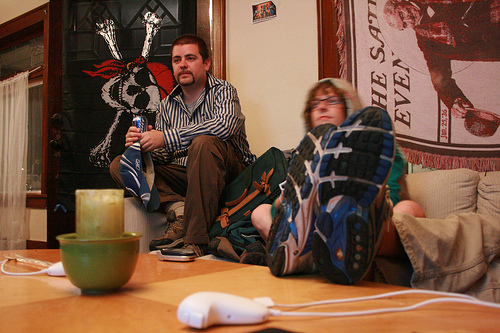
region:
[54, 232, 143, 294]
green bowl on coffee table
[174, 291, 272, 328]
white Wii nunchuck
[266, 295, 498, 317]
white wire attached to Wii nunchuck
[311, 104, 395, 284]
sole of shoe is black and blue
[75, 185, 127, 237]
green candle in green bowl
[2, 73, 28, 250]
sheer white curtain is hanging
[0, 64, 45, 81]
curtain on curtain rod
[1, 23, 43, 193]
curtain on window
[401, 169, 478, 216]
tan sofa cushion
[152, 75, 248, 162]
striped long sleeve shirt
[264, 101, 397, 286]
bottoms of woman's sneakers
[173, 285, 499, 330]
white wii remote on a coffee table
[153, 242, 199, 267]
cell phone on a coffee table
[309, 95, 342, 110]
glasses on a person's face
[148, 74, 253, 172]
person's black and white striped shirt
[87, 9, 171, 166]
sideways pirate emblem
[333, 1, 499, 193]
throw hanging on wall sideways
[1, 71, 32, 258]
sheer white curtain hanging over window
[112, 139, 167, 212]
blue and white baseball cap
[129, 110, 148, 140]
can of beer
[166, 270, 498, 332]
game controller on table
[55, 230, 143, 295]
green bowl sitting on table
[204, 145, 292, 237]
green and brown luggage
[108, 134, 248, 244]
man's brown pants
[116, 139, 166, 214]
baseball hat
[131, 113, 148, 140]
blue and silver beer can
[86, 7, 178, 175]
red and white and black pirate symbol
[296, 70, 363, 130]
hood on person's head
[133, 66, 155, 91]
patch on the pirate's eye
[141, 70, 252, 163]
man's black and white shirt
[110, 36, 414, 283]
two people sitting near each other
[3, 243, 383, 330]
white game controllers on brown surface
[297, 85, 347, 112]
person wearing glasses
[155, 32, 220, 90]
man has dark hair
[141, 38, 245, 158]
man wearing a striped dress shirt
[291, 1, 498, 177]
rug with fringe on wall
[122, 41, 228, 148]
man holding an aluminum can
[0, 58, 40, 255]
sheer curtain in front of window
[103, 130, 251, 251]
man is wearing dark brown pants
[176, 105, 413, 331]
person's feet near game controller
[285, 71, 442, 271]
a person wearing glasses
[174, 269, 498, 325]
a white controller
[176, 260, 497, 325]
a white controller with a white cord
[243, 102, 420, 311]
athletic sneakers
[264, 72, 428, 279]
a person wearing athletic sneakers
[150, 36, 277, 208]
a man with facial hair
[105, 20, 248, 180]
a person holding a beer can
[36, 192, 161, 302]
a green cup on a table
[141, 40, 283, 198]
a man wearing a striped shirt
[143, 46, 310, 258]
a person wearing pants